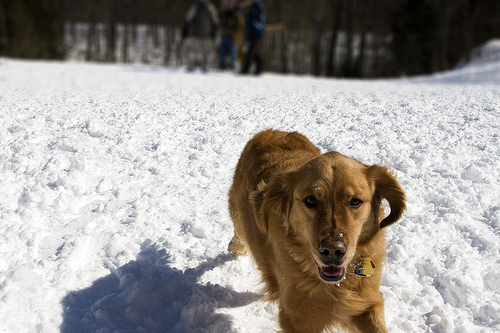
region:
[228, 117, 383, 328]
A dog in the snow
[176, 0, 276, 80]
A group of people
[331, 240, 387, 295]
tags on the dog's collar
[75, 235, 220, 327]
The shadow of the dog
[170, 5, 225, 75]
A man in a black and white snow suit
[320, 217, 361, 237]
snow on the dog's nose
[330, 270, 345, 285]
snow on the dog's chin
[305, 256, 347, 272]
the dog's tongue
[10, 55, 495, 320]
The ground covered in snow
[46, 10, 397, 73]
a large group of trees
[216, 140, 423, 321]
The dog is looking at the camera.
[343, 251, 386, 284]
The dog has on a silver name tag.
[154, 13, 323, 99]
People are standing behind the dog.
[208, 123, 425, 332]
The dog is brown.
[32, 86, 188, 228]
The white snow is fluffy.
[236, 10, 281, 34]
A person is wearing a blue jacket.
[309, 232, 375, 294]
The dog has his mouth open.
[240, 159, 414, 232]
The dog ears are curvy.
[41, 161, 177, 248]
Footprints are in the snow.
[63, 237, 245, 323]
The dog shadow is in the snow.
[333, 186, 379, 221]
a dog's left eye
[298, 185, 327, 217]
a dog's right eye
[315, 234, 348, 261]
a dog's brown nose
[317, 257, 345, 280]
a dog's pink tounge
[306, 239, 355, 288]
a dogs small mouth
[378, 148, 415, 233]
a dog's left ear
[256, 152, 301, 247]
a dog's right ear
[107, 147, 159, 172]
this is the snow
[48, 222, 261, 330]
this is a shadow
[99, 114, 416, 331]
this is a dog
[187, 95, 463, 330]
A dog in the snow.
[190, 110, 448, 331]
The dog's fur is orange.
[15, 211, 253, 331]
The dog created a shadow on the snow.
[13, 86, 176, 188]
Sun shining on the snow.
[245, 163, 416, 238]
The dog has two floppy ears.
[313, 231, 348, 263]
The dog has a light brown nose.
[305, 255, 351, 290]
The dog's mouth is open.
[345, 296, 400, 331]
Part of the dog's front leg is visible.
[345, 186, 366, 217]
An eye on a dog.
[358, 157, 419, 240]
An ear on a dog.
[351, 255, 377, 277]
a tag on a dog's neck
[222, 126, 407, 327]
a golden dog running in the snow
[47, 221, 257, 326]
the shadow of a dog on the snow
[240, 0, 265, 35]
a blue and black jacket on a person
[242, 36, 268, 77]
black pants on a person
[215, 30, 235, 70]
blue pants on a person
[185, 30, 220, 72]
grey pants on a person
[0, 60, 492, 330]
white trampled snow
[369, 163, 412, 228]
an ear on a dog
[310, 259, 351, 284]
an open mouth on a dog